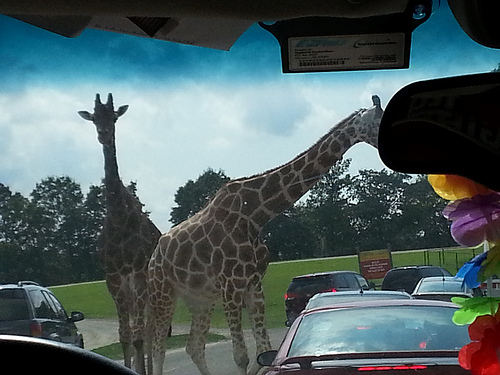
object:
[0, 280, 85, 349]
minivan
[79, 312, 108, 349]
road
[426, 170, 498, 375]
stuff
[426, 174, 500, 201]
flower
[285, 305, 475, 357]
windshield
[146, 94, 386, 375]
animal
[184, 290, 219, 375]
leg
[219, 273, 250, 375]
leg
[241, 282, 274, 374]
leg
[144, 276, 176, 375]
leg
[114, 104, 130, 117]
ear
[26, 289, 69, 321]
windows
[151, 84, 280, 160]
sky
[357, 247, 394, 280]
sign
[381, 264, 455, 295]
car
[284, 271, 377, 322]
car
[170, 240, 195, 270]
spot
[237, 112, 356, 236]
neck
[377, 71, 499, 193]
mirror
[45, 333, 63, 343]
wheel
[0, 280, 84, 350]
car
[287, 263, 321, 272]
grass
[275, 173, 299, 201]
spot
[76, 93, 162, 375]
giraffe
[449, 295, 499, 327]
green flower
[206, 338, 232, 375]
road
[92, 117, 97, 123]
eyes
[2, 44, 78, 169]
sky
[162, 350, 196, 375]
road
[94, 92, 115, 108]
horns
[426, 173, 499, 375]
lei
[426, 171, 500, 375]
colorful lei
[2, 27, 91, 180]
clouds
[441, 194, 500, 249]
purple flower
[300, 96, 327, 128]
clouds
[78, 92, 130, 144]
head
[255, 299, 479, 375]
back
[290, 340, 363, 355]
light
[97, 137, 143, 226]
neck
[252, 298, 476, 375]
car